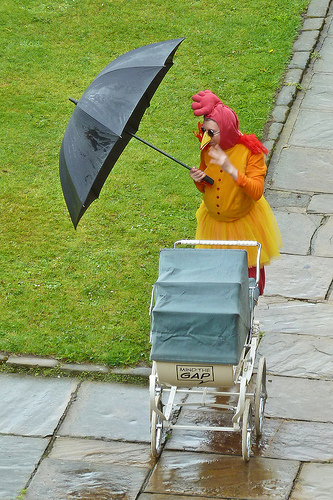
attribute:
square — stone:
[76, 371, 173, 454]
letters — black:
[175, 362, 210, 382]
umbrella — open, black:
[56, 41, 219, 229]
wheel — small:
[240, 398, 252, 461]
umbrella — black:
[49, 31, 188, 232]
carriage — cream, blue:
[147, 239, 266, 463]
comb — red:
[183, 89, 264, 156]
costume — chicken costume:
[189, 87, 271, 276]